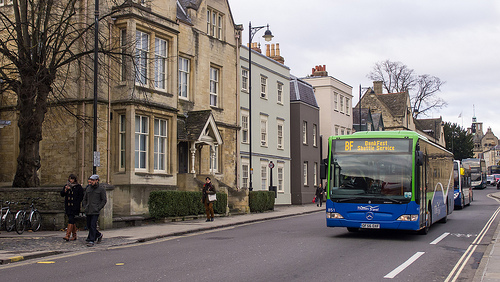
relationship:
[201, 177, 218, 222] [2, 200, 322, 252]
person walking on pavement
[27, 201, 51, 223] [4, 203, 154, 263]
bicycle parked on pavement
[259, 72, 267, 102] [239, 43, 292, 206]
window on building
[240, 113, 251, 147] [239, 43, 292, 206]
window on building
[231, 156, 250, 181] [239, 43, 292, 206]
window on building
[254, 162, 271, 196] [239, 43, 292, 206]
window on building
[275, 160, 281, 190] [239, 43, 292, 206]
window on building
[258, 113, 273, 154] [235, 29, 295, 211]
window on building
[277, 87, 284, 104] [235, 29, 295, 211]
window on building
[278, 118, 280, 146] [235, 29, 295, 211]
window on building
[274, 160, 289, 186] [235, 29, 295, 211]
window on building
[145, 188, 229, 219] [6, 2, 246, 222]
hedges in front of residence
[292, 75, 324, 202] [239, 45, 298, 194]
building by lighter building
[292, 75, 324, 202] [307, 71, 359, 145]
building by lighter building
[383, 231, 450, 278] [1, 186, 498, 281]
broken lines on road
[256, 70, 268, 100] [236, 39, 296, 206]
window on building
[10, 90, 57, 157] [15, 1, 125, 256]
trunk of tree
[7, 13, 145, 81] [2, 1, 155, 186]
branches of tree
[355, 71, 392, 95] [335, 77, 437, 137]
chimney on house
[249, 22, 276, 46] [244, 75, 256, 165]
street light on pole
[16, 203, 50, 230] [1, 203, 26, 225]
bike beside bike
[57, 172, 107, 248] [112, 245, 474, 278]
people walking down street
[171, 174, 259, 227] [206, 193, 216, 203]
person holding bag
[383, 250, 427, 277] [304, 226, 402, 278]
broken lines on road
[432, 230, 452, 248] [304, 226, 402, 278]
line on road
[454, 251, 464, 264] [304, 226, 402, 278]
line on road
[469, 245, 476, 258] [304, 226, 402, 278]
line on road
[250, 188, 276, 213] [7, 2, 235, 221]
hedge in front of building